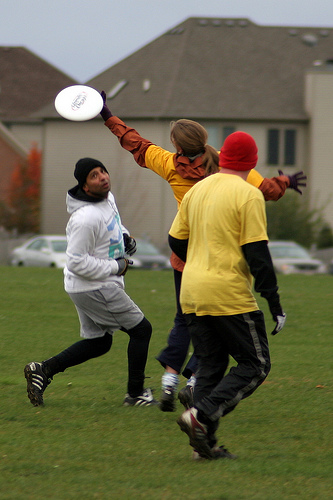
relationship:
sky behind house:
[4, 0, 328, 47] [0, 7, 316, 232]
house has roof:
[27, 15, 331, 257] [31, 16, 330, 125]